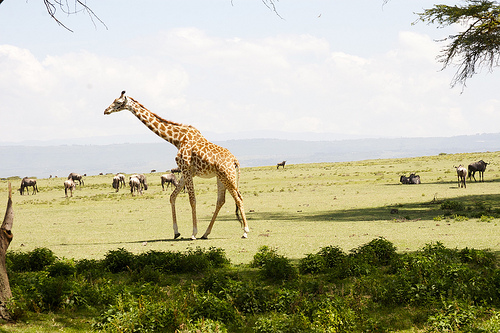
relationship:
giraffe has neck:
[101, 88, 252, 241] [137, 104, 177, 146]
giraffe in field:
[101, 88, 252, 241] [2, 147, 499, 332]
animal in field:
[454, 161, 474, 194] [2, 147, 499, 332]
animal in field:
[468, 153, 484, 183] [2, 147, 499, 332]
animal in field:
[272, 150, 290, 168] [2, 147, 499, 332]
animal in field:
[59, 177, 76, 201] [2, 147, 499, 332]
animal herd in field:
[8, 157, 491, 197] [3, 148, 494, 251]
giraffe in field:
[101, 88, 252, 241] [3, 148, 494, 251]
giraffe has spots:
[101, 88, 252, 241] [174, 133, 214, 163]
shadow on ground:
[196, 193, 498, 221] [20, 196, 497, 331]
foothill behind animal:
[330, 171, 425, 201] [100, 89, 253, 244]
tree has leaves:
[408, 1, 496, 95] [409, 2, 498, 92]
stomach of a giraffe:
[193, 166, 217, 180] [94, 79, 306, 219]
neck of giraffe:
[137, 104, 177, 146] [101, 88, 252, 241]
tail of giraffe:
[233, 172, 254, 211] [98, 84, 260, 252]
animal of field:
[125, 174, 142, 197] [2, 147, 499, 332]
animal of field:
[272, 150, 290, 168] [2, 147, 499, 332]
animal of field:
[392, 164, 424, 184] [2, 147, 499, 332]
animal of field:
[454, 161, 474, 194] [2, 147, 499, 332]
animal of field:
[468, 153, 484, 183] [2, 147, 499, 332]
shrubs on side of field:
[2, 237, 499, 331] [5, 172, 481, 281]